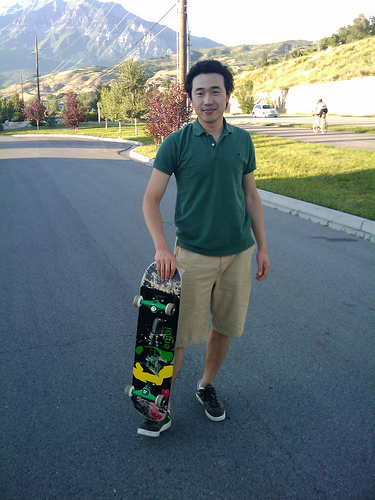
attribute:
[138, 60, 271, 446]
man — posing, standing, asian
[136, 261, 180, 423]
skateboard — black, multicolored, yellow, green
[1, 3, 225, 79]
mountain — large, rocky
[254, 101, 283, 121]
car — white, moving, parked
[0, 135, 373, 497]
road — ending, asphalt, grey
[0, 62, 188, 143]
trees — small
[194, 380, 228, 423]
shoe — black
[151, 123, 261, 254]
shirt — green, polo, aqua blue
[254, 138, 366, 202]
grass — green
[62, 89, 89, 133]
tree — red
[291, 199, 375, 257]
curb — concrete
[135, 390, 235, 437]
shoes — black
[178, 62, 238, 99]
hair — dark, black, curly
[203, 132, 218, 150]
buttons — white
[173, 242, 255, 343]
shorts — tan, khaki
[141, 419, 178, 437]
trim — white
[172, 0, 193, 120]
pole — telephone